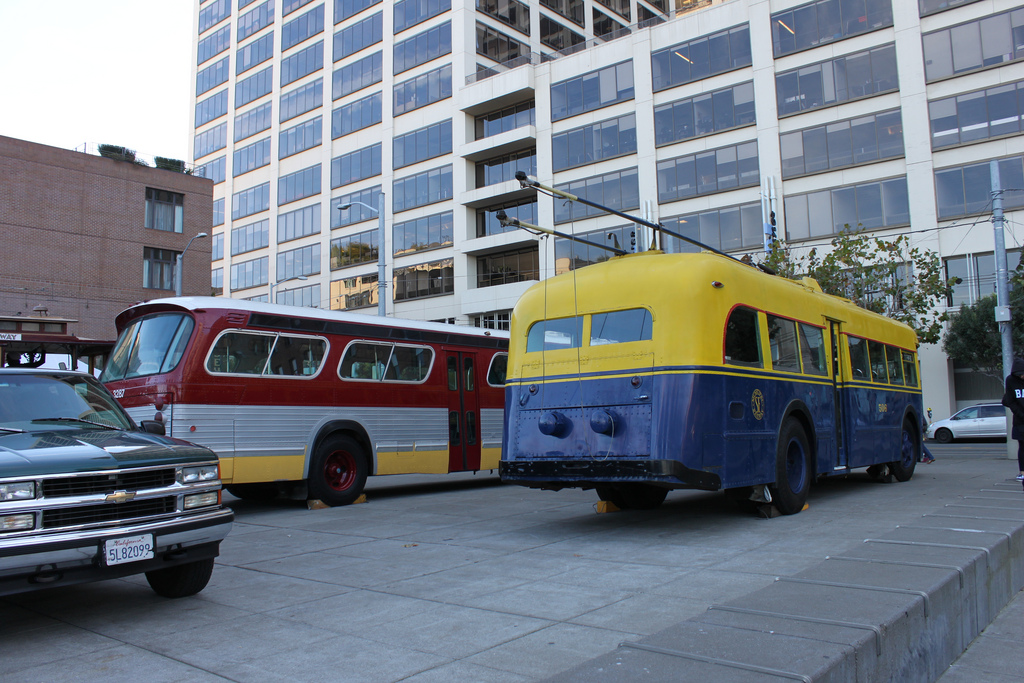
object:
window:
[546, 54, 636, 130]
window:
[778, 172, 910, 245]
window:
[755, 5, 908, 60]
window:
[639, 20, 760, 96]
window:
[543, 104, 650, 177]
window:
[650, 77, 767, 146]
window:
[462, 87, 538, 138]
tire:
[892, 430, 924, 476]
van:
[915, 396, 1013, 447]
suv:
[0, 366, 235, 596]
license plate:
[105, 535, 154, 564]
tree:
[796, 224, 968, 358]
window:
[380, 68, 462, 110]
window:
[272, 159, 333, 200]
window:
[541, 214, 656, 275]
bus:
[88, 264, 496, 512]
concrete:
[3, 440, 1022, 672]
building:
[184, 0, 534, 517]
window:
[588, 304, 655, 347]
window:
[714, 304, 766, 368]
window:
[103, 310, 190, 379]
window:
[339, 333, 435, 382]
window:
[210, 324, 331, 378]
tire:
[306, 417, 375, 502]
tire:
[570, 468, 679, 525]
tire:
[770, 403, 817, 525]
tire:
[135, 527, 222, 598]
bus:
[495, 232, 957, 514]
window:
[391, 263, 462, 302]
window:
[395, 162, 485, 215]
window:
[462, 239, 538, 287]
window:
[315, 83, 402, 140]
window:
[456, 141, 547, 192]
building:
[2, 131, 218, 372]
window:
[232, 59, 275, 108]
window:
[234, 28, 288, 76]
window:
[191, 89, 227, 128]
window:
[195, 23, 234, 65]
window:
[198, 0, 231, 30]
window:
[143, 243, 184, 294]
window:
[327, 273, 391, 316]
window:
[139, 181, 185, 231]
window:
[224, 250, 281, 295]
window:
[762, 311, 806, 370]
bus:
[492, 251, 921, 512]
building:
[172, 11, 991, 444]